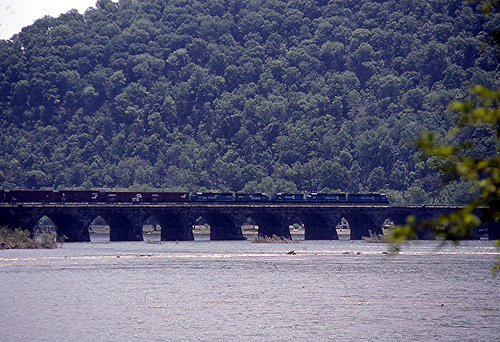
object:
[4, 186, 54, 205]
car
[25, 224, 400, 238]
shoreline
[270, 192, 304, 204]
train car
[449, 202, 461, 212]
tracks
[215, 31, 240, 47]
trees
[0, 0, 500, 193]
hill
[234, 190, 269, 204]
train car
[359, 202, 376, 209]
tracks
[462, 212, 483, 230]
leaves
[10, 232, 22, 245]
bushes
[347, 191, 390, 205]
car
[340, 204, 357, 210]
tracks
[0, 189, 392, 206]
train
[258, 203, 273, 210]
tracks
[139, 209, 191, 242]
arch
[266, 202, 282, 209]
tracks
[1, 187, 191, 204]
cargo cars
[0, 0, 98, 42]
sky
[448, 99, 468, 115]
leaves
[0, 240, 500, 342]
water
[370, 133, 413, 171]
tree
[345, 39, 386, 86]
tree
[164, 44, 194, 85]
tree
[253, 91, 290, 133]
tree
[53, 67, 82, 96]
tree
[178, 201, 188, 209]
tracks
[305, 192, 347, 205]
car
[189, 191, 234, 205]
car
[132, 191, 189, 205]
car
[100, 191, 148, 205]
car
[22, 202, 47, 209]
tracks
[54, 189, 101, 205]
train car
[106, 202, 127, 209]
tracks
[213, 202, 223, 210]
tracks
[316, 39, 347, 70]
trees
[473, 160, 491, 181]
branches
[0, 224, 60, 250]
grass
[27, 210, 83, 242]
arch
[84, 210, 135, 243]
arch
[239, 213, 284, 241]
arch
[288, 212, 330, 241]
arch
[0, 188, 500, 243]
bridge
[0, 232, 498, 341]
water